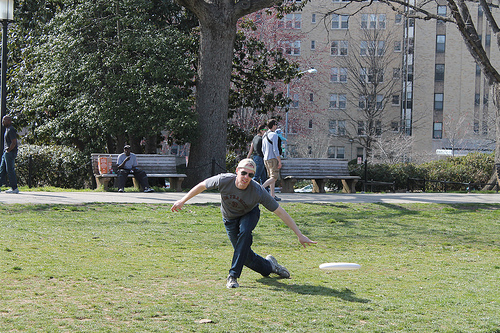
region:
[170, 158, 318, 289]
Man playing Frisbee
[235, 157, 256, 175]
Hat on the man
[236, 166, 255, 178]
Sunglasses on the man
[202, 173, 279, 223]
Shirt on the man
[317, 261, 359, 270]
White Frisbee in the air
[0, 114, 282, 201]
People walking on the road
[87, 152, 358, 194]
Benches on the side of the road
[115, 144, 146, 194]
Man sitting on the bench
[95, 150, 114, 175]
Bag on the bench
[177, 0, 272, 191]
Big tree between the benches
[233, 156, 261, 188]
head of a person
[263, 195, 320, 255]
arm of a person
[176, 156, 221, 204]
arm of a person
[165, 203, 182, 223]
hand of a person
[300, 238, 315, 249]
hand of a person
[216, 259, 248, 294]
feet of a person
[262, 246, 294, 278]
feet of a person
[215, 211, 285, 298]
leg of a person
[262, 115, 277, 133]
head of a person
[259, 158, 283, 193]
leg of a person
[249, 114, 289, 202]
they are walking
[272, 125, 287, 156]
he is carrying a baby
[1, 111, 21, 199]
the guy is walking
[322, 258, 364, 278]
the frisbee is white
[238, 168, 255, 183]
he is wearing sunglasses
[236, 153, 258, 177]
the hat is on backwards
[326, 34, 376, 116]
the building has a lot of windows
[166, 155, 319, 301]
A man playing frisbee in park.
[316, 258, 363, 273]
White frisbee being tossed to man.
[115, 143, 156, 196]
Man sitting on a bench and eating.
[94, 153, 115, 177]
Orange shopping bag on a bench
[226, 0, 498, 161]
Tan apartment building beside park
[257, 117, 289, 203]
Man hold baby in carrier on his chest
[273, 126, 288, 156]
Baby in a carrier on a man's chest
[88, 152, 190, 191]
Bench in the park beside a tree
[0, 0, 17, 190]
Tall black lamp post in park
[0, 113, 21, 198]
Man walking on path in park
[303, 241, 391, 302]
frisbee in the air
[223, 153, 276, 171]
man's hat is on backwards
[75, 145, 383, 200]
two benches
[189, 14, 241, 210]
large tree between the benches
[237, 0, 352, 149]
pink flowers on the tree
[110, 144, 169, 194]
man sitting on a bench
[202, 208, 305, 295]
man's legs are crossed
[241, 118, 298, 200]
couple walking on the sidewalk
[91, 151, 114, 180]
bag on the bench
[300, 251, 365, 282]
frisbee in the air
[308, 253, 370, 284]
the frisbee is white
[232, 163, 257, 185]
a pair of sunglasses